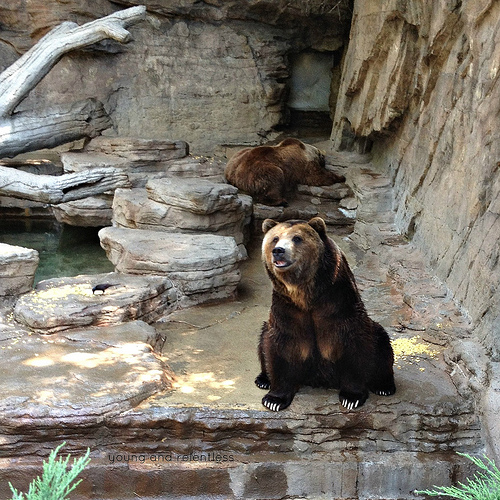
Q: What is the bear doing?
A: Looking forward.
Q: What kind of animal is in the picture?
A: Bears.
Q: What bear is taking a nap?
A: Bear in the background.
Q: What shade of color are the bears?
A: Brown.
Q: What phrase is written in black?
A: Young and relentless.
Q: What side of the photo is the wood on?
A: Left side.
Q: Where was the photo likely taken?
A: Zoo.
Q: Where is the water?
A: Under the wood structure.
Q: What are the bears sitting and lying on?
A: Rocks.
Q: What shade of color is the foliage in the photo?
A: Green.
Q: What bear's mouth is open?
A: The bear in front.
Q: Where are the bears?
A: On the rocks.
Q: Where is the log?
A: Above the water.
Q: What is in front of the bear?
A: Water.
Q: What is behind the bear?
A: Another bear.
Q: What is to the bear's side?
A: Rock.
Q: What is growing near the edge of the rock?
A: Green plants.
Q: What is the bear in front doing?
A: Sitting.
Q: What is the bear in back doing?
A: Lying down.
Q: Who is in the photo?
A: Nobody.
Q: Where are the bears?
A: In a zoo.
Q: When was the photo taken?
A: Daytime.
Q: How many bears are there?
A: Two.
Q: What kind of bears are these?
A: Grizzlies.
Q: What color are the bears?
A: Brown.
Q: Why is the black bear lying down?
A: It's napping.